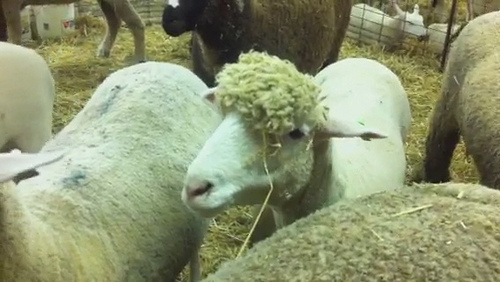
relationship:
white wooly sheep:
[218, 47, 348, 217] [214, 63, 339, 143]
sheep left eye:
[180, 58, 412, 230] [282, 121, 318, 144]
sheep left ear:
[180, 58, 412, 230] [304, 91, 391, 150]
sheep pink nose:
[180, 58, 412, 230] [179, 173, 220, 208]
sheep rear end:
[180, 58, 412, 230] [340, 45, 435, 99]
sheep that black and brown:
[214, 63, 339, 143] [180, 11, 328, 60]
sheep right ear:
[180, 58, 412, 230] [194, 71, 234, 126]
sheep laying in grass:
[214, 63, 339, 143] [364, 8, 436, 52]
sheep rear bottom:
[180, 58, 412, 230] [91, 0, 144, 61]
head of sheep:
[218, 47, 348, 217] [214, 63, 339, 143]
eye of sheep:
[282, 121, 318, 144] [214, 63, 339, 143]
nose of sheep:
[179, 173, 220, 208] [214, 63, 339, 143]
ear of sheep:
[304, 91, 391, 150] [214, 63, 339, 143]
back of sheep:
[312, 44, 434, 120] [214, 63, 339, 143]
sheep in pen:
[214, 63, 339, 143] [65, 5, 396, 147]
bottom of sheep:
[91, 0, 144, 61] [214, 63, 339, 143]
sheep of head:
[180, 58, 412, 230] [200, 109, 337, 158]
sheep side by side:
[180, 58, 412, 230] [109, 26, 341, 155]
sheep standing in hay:
[180, 58, 412, 230] [65, 5, 396, 147]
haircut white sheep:
[212, 49, 329, 137] [214, 63, 339, 143]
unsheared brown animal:
[180, 11, 328, 60] [162, 2, 282, 36]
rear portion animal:
[265, 8, 392, 57] [162, 2, 282, 36]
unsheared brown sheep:
[180, 5, 318, 35] [214, 63, 339, 143]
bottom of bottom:
[69, 6, 176, 79] [91, 0, 144, 61]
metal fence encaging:
[382, 16, 438, 56] [364, 8, 436, 52]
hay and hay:
[61, 33, 107, 76] [50, 33, 107, 76]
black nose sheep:
[169, 11, 237, 35] [214, 63, 339, 143]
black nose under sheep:
[161, 12, 180, 36] [214, 63, 339, 143]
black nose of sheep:
[161, 12, 180, 36] [214, 63, 339, 143]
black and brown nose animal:
[180, 11, 328, 60] [162, 0, 353, 88]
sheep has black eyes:
[214, 63, 339, 143] [167, 3, 217, 21]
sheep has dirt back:
[214, 63, 339, 143] [99, 60, 155, 108]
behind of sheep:
[265, 8, 392, 57] [214, 63, 339, 143]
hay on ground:
[61, 33, 107, 76] [77, 44, 149, 136]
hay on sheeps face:
[61, 33, 107, 76] [220, 132, 298, 196]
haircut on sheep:
[200, 41, 350, 178] [214, 63, 339, 143]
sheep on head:
[214, 63, 339, 143] [173, 50, 394, 219]